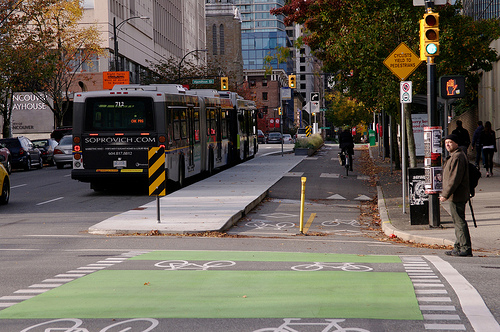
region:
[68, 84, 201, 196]
a public service bus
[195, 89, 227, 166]
a public service bus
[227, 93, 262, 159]
a public service bus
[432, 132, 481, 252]
a pedestrian on street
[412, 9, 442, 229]
a green traffic signal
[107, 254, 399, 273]
a bicycle crossing lane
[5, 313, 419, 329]
a bicycle crossing lane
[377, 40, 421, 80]
a yellow traffic sign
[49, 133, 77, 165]
a parked silver car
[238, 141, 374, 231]
two way bicycle only lanes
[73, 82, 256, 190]
The bus is large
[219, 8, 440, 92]
Stop lights are green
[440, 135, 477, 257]
Person is waiting at crosswalk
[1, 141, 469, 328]
Bike land section off road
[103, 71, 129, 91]
Orange sign on black pole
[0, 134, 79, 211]
Cars beside bus on street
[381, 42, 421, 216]
Orange street sign on metal pole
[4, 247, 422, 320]
Street has green squares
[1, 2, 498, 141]
Large buildings line background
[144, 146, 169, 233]
Yellow black caution sign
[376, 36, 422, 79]
The sign for cyclists.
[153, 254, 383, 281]
Bikes on the ground.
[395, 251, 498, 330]
A white cross walk on road.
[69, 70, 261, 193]
A bus on the road.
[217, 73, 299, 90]
The street lights are green.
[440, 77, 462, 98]
A hand is signalling.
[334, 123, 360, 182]
A person rides away.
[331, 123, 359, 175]
A person rides a bike.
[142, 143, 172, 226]
A yellow and black sign.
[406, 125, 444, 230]
Stickers on the light, and trash can.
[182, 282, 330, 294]
green paint in crosswalk.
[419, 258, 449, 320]
white paint on the road.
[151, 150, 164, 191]
yellow and black sign.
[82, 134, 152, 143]
writing on the bus.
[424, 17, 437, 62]
traffic light on pole.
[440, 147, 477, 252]
man standing on the corner.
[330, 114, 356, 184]
person on a bicycle.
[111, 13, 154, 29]
street light on pole.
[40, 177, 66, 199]
shadow on the road.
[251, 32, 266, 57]
glass windows on building.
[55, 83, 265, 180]
a white car on a street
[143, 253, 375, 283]
designs of a bike on right side of street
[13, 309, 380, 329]
designs of a bike on left side of street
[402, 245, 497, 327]
crossing lines on a street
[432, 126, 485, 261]
man holdings a backpack on left shoulder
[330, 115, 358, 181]
person riding a bike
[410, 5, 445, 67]
traffic light on a pole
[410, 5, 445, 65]
traffic light is on green light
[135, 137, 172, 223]
a street sign yellow and black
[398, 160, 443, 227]
trash can next to a traffic light